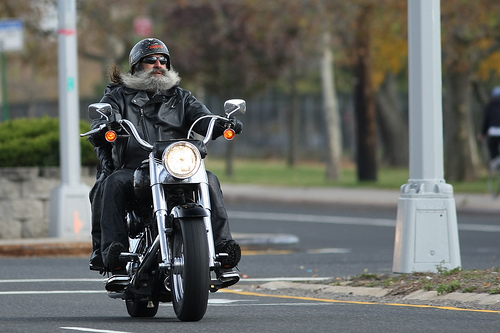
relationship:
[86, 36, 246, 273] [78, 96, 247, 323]
man on a motor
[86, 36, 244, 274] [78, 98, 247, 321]
man riding motor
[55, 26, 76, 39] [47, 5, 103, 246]
sticker on light post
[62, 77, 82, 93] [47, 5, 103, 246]
sticker on light post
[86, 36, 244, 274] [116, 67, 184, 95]
man has beard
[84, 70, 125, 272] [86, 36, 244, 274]
person sitting behind man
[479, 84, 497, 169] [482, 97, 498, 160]
person wearing outfit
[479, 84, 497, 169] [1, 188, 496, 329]
person walking by street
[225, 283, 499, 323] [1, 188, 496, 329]
line on street